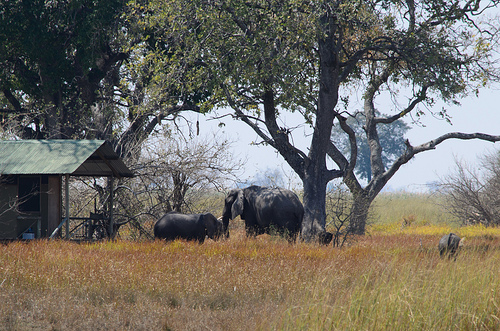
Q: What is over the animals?
A: Trees.